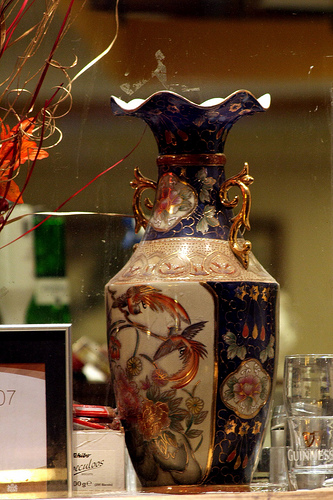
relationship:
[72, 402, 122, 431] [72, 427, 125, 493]
candybars on box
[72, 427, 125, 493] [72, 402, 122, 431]
box with candybars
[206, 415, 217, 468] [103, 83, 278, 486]
stripe on vase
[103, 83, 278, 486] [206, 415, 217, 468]
vase with stripe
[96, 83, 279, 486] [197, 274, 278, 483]
vase with panel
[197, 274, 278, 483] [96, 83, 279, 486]
panel on vase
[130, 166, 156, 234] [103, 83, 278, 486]
accent on vase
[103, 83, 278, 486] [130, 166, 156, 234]
vase with accent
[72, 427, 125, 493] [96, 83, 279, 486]
box next to vase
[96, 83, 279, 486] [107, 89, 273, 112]
vase with mouth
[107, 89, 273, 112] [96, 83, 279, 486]
mouth of vase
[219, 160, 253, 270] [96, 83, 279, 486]
accent of vase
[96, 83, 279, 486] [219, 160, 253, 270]
vase with accent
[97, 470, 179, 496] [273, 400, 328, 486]
table with glass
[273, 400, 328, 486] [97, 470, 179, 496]
glass on table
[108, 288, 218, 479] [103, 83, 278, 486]
flower on vase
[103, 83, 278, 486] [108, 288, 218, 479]
vase with flower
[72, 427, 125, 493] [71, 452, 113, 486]
box with writing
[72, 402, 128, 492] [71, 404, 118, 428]
box filled with matches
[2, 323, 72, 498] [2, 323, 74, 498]
picture in frame